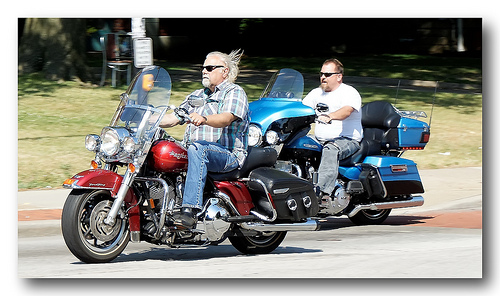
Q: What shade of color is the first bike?
A: Red.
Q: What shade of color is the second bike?
A: Blue.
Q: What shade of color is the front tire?
A: Black.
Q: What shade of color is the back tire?
A: Black.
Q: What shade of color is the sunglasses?
A: Black.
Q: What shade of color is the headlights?
A: Silver.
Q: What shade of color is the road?
A: Gray.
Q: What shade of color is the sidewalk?
A: Gray.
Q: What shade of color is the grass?
A: Green.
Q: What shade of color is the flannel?
A: Blue.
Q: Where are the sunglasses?
A: On the men's faces.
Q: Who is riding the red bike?
A: An older man with grey hair and beard.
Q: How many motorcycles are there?
A: 2.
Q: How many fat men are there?
A: 2.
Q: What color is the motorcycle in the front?
A: Red.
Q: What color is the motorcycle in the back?
A: Blue.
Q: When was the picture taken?
A: Noon.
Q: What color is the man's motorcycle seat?
A: Black.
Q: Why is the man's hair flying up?
A: Wind.